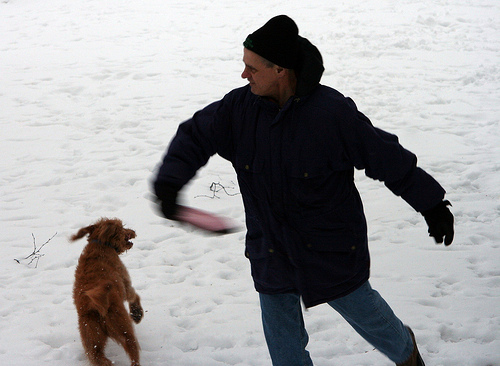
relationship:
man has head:
[148, 13, 454, 366] [234, 30, 332, 96]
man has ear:
[148, 13, 454, 366] [275, 55, 295, 79]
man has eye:
[148, 13, 454, 366] [240, 56, 272, 82]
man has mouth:
[148, 13, 454, 366] [243, 75, 260, 85]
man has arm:
[148, 13, 454, 366] [156, 95, 226, 199]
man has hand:
[148, 13, 454, 366] [417, 187, 458, 248]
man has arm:
[148, 13, 454, 366] [325, 89, 499, 255]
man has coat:
[148, 13, 454, 366] [151, 88, 441, 309]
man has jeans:
[141, 13, 471, 351] [259, 270, 412, 363]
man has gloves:
[148, 13, 454, 366] [381, 189, 493, 259]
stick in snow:
[12, 230, 58, 271] [0, 23, 143, 153]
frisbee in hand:
[158, 193, 238, 240] [411, 199, 459, 247]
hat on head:
[241, 12, 308, 72] [241, 14, 299, 96]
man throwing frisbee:
[141, 13, 471, 351] [157, 191, 244, 239]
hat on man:
[241, 12, 308, 72] [191, 29, 389, 304]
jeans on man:
[252, 278, 428, 364] [141, 13, 471, 351]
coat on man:
[151, 88, 441, 309] [141, 13, 471, 351]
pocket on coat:
[316, 241, 371, 298] [185, 80, 426, 290]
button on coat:
[266, 246, 273, 251] [151, 88, 441, 309]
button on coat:
[241, 161, 251, 176] [151, 88, 441, 309]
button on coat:
[346, 235, 359, 255] [151, 88, 441, 309]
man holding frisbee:
[148, 13, 454, 366] [167, 198, 240, 235]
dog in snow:
[68, 215, 143, 365] [1, 0, 498, 361]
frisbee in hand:
[171, 206, 244, 235] [150, 190, 289, 265]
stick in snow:
[12, 229, 57, 271] [4, 5, 143, 205]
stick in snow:
[200, 175, 239, 203] [4, 5, 143, 205]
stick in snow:
[188, 182, 239, 199] [0, 0, 146, 215]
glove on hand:
[424, 202, 450, 241] [418, 202, 457, 248]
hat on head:
[246, 17, 324, 84] [238, 14, 299, 96]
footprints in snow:
[21, 24, 93, 84] [1, 0, 498, 361]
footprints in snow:
[408, 10, 493, 56] [1, 0, 498, 361]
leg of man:
[258, 292, 313, 364] [148, 13, 454, 366]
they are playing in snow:
[46, 10, 459, 363] [1, 0, 498, 361]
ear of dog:
[70, 221, 100, 242] [64, 220, 151, 360]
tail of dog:
[85, 283, 111, 319] [68, 214, 148, 358]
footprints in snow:
[438, 260, 487, 295] [443, 311, 486, 338]